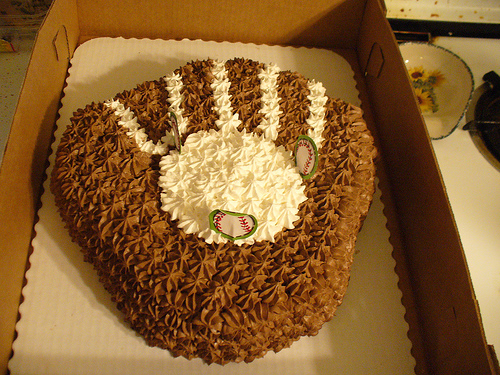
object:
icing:
[103, 99, 162, 154]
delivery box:
[0, 0, 497, 373]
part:
[30, 72, 52, 123]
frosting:
[48, 56, 381, 361]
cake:
[50, 54, 377, 366]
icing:
[177, 265, 245, 309]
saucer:
[388, 40, 474, 140]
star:
[215, 109, 242, 134]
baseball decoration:
[292, 136, 319, 180]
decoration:
[170, 109, 183, 152]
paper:
[335, 328, 415, 374]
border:
[436, 191, 472, 296]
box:
[0, 2, 498, 374]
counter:
[391, 26, 498, 366]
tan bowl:
[397, 38, 476, 139]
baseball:
[208, 206, 259, 240]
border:
[311, 138, 317, 181]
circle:
[156, 120, 310, 243]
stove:
[465, 67, 500, 174]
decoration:
[209, 211, 257, 242]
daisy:
[420, 65, 446, 90]